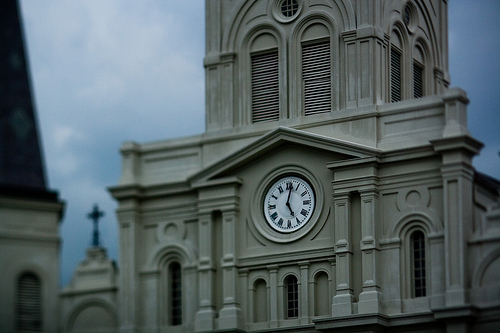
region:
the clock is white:
[257, 166, 313, 258]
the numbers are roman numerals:
[268, 180, 311, 228]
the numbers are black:
[266, 178, 311, 230]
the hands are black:
[281, 184, 298, 216]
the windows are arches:
[155, 210, 437, 331]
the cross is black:
[86, 201, 111, 248]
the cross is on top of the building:
[83, 198, 110, 250]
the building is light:
[108, 2, 496, 330]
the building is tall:
[99, 52, 476, 332]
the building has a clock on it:
[256, 166, 333, 244]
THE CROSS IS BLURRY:
[76, 195, 119, 268]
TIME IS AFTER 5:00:
[250, 165, 330, 250]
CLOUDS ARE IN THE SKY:
[44, 16, 186, 123]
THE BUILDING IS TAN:
[339, 97, 464, 222]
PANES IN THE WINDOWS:
[284, 275, 301, 319]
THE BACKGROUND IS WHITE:
[264, 177, 287, 239]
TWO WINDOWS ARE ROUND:
[266, 0, 422, 37]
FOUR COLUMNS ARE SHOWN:
[190, 175, 380, 318]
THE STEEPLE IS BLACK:
[0, 2, 77, 224]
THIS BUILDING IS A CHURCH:
[108, 12, 481, 315]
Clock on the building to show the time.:
[248, 148, 328, 252]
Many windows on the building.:
[145, 236, 476, 326]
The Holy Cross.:
[82, 192, 108, 253]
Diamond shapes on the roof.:
[6, 44, 42, 164]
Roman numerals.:
[269, 169, 309, 233]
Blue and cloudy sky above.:
[45, 34, 179, 132]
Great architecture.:
[114, 105, 499, 320]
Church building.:
[8, 8, 498, 331]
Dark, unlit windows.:
[149, 218, 490, 312]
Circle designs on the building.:
[395, 184, 437, 211]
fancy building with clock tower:
[25, 9, 432, 329]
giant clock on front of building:
[202, 124, 395, 304]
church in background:
[66, 182, 163, 311]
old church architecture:
[2, 2, 434, 325]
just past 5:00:
[228, 129, 382, 283]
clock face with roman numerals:
[229, 137, 353, 272]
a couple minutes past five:
[248, 141, 350, 293]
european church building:
[99, 118, 437, 329]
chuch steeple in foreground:
[0, 25, 125, 321]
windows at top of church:
[198, 4, 455, 132]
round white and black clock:
[251, 168, 323, 237]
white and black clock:
[251, 166, 322, 237]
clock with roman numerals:
[251, 165, 323, 237]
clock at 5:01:
[248, 172, 321, 242]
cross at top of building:
[72, 200, 114, 269]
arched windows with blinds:
[240, 15, 344, 120]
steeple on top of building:
[0, 0, 47, 212]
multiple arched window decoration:
[379, 217, 443, 316]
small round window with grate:
[271, 0, 303, 25]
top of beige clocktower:
[91, 2, 495, 331]